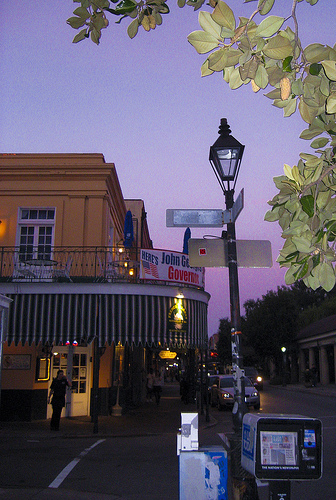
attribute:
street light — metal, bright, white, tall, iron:
[206, 115, 248, 433]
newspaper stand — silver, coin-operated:
[236, 410, 325, 500]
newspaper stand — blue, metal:
[172, 410, 232, 500]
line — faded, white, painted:
[47, 434, 108, 490]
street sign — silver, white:
[163, 207, 229, 230]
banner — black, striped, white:
[0, 292, 210, 350]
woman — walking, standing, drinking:
[46, 367, 73, 435]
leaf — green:
[301, 195, 316, 218]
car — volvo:
[208, 373, 261, 409]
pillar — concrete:
[91, 340, 101, 435]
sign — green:
[162, 302, 191, 334]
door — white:
[47, 346, 95, 418]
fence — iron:
[0, 245, 206, 292]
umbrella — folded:
[124, 207, 138, 278]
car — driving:
[239, 364, 265, 390]